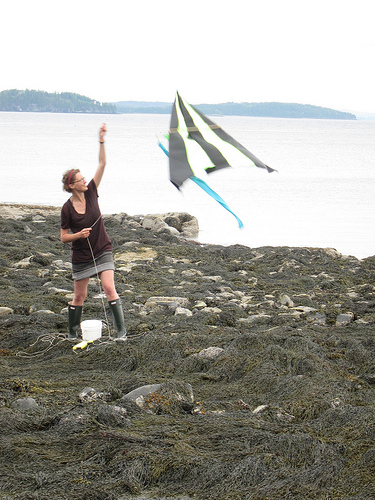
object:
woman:
[54, 119, 129, 343]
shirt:
[59, 177, 115, 268]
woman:
[55, 105, 134, 364]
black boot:
[106, 292, 128, 343]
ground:
[334, 68, 351, 83]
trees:
[0, 89, 58, 109]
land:
[114, 100, 355, 120]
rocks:
[126, 212, 197, 239]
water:
[0, 110, 373, 176]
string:
[15, 210, 128, 360]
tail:
[154, 135, 247, 230]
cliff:
[2, 199, 357, 500]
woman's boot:
[104, 295, 130, 344]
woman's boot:
[66, 299, 87, 343]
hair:
[60, 164, 83, 196]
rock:
[121, 382, 193, 413]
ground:
[0, 204, 372, 495]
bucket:
[80, 316, 101, 341]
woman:
[39, 149, 159, 344]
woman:
[41, 144, 149, 351]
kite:
[152, 87, 288, 235]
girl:
[56, 120, 134, 345]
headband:
[65, 165, 76, 187]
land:
[0, 226, 359, 497]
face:
[69, 167, 89, 194]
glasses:
[70, 175, 87, 182]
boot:
[63, 300, 86, 343]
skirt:
[68, 251, 117, 281]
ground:
[12, 360, 317, 495]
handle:
[72, 335, 94, 351]